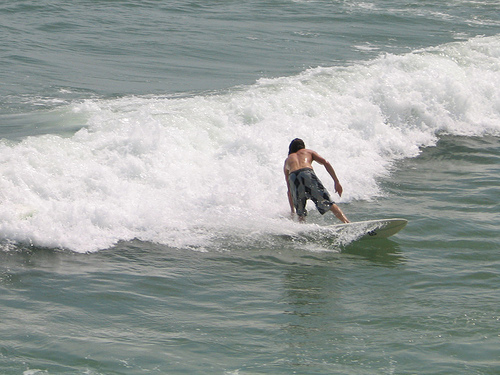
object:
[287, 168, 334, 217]
shorts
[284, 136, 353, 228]
man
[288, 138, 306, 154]
hair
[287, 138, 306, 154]
head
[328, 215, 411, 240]
surfboard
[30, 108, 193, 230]
wave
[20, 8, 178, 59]
water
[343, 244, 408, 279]
shadow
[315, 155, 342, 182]
arm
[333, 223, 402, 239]
bottom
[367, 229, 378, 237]
logo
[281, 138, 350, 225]
back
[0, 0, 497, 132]
ocean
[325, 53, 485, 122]
waves